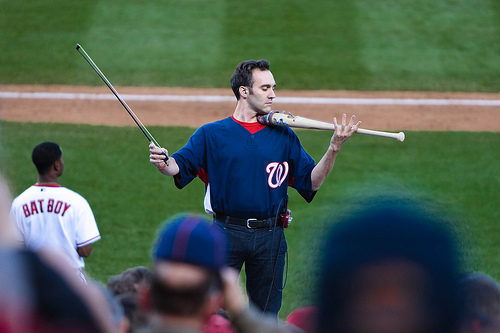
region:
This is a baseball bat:
[257, 86, 413, 164]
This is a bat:
[245, 64, 440, 250]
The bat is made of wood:
[263, 96, 412, 190]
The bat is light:
[263, 123, 418, 149]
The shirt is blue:
[221, 79, 296, 291]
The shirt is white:
[70, 195, 98, 257]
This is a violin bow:
[45, 12, 182, 122]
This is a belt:
[264, 201, 277, 238]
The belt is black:
[228, 198, 297, 255]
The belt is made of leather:
[240, 201, 277, 271]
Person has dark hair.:
[238, 54, 287, 111]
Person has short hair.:
[227, 50, 279, 94]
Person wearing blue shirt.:
[194, 135, 292, 195]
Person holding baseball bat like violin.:
[315, 118, 354, 189]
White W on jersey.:
[263, 138, 290, 183]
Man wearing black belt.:
[221, 204, 293, 237]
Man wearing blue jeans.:
[241, 233, 298, 278]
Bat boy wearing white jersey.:
[16, 183, 111, 249]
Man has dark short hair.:
[31, 140, 79, 182]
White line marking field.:
[114, 53, 424, 140]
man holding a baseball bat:
[228, 93, 435, 165]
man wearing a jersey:
[1, 182, 110, 271]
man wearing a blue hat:
[151, 209, 247, 277]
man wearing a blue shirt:
[177, 108, 312, 215]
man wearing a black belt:
[217, 208, 292, 228]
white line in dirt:
[6, 85, 216, 114]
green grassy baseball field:
[96, 8, 195, 49]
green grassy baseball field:
[304, 3, 404, 63]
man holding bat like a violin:
[64, 12, 444, 191]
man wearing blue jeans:
[214, 205, 303, 318]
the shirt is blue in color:
[181, 115, 310, 214]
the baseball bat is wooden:
[265, 100, 408, 141]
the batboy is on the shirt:
[13, 188, 74, 220]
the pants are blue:
[224, 218, 294, 308]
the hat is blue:
[151, 218, 237, 273]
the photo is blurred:
[320, 203, 479, 328]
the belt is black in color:
[218, 210, 275, 229]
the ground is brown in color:
[395, 106, 485, 123]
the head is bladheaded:
[144, 260, 216, 288]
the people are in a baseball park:
[1, 34, 483, 324]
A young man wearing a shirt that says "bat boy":
[2, 138, 107, 291]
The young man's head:
[25, 139, 70, 183]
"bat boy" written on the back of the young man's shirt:
[19, 195, 76, 217]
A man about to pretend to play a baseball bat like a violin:
[71, 32, 412, 327]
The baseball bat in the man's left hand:
[252, 106, 407, 144]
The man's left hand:
[330, 110, 361, 142]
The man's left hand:
[310, 110, 364, 194]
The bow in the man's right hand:
[70, 41, 170, 169]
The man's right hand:
[145, 138, 170, 170]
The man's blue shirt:
[165, 114, 327, 218]